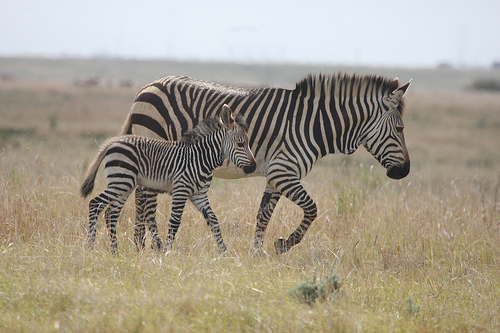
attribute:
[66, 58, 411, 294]
zebra — mare, baby, adult, foal, female, leg, head, tail, nose, walk, ear, beautiful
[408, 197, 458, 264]
grass — tall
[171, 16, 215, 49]
sky — back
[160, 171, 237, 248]
leg — raised